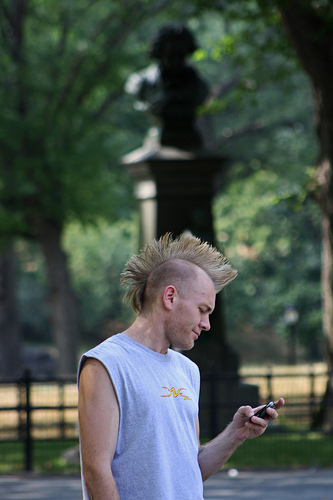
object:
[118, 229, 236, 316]
hair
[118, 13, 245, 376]
statue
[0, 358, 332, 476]
fence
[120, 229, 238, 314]
mohawk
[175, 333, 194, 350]
chin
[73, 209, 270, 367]
man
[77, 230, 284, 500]
man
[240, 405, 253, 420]
fingers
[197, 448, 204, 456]
tattoo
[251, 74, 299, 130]
ground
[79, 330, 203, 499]
shirt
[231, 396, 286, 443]
hand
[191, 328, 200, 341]
mouth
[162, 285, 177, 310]
ear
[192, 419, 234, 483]
arm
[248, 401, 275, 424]
cell phone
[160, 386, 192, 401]
graphics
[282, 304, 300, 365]
street lamp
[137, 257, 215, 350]
head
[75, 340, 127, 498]
arm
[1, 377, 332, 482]
railing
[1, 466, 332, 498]
pavement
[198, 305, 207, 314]
eye